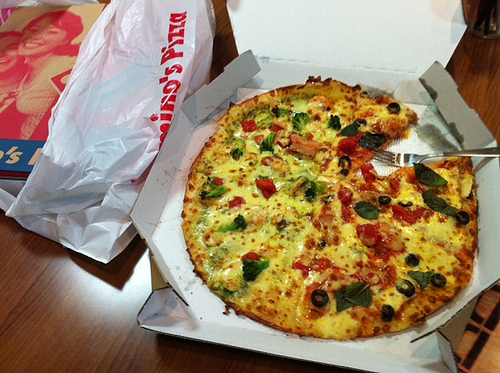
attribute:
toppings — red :
[274, 229, 406, 317]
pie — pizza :
[182, 76, 482, 336]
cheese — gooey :
[273, 239, 305, 266]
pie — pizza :
[184, 80, 466, 317]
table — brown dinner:
[6, 255, 111, 346]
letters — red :
[155, 9, 183, 155]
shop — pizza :
[7, 9, 484, 353]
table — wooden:
[5, 4, 495, 369]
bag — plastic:
[7, 1, 225, 273]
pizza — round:
[181, 76, 481, 351]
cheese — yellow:
[182, 80, 475, 344]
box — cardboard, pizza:
[122, 4, 498, 372]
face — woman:
[15, 16, 69, 64]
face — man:
[4, 32, 28, 80]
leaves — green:
[329, 274, 380, 318]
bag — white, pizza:
[1, 4, 211, 266]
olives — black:
[377, 189, 390, 203]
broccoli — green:
[197, 176, 232, 204]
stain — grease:
[411, 119, 461, 159]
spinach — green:
[405, 152, 454, 232]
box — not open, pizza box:
[2, 21, 190, 202]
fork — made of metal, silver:
[355, 134, 498, 170]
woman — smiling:
[5, 10, 99, 81]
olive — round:
[297, 281, 347, 321]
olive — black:
[303, 287, 343, 317]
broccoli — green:
[223, 260, 283, 283]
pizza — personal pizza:
[173, 66, 498, 343]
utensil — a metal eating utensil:
[342, 140, 498, 172]